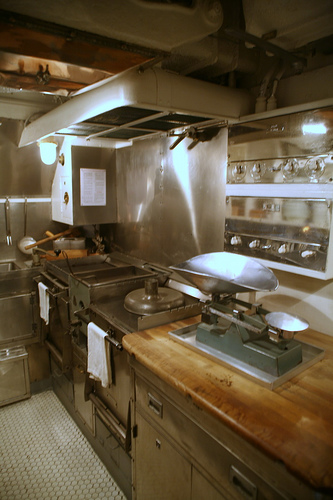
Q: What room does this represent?
A: It represents the kitchen.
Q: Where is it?
A: This is at the kitchen.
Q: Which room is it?
A: It is a kitchen.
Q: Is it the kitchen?
A: Yes, it is the kitchen.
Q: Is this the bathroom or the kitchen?
A: It is the kitchen.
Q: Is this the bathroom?
A: No, it is the kitchen.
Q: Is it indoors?
A: Yes, it is indoors.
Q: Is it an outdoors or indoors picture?
A: It is indoors.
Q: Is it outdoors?
A: No, it is indoors.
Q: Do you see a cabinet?
A: Yes, there is a cabinet.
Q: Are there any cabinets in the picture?
A: Yes, there is a cabinet.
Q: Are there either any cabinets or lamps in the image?
A: Yes, there is a cabinet.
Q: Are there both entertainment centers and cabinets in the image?
A: No, there is a cabinet but no entertainment centers.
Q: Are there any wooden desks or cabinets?
A: Yes, there is a wood cabinet.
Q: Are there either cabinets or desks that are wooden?
A: Yes, the cabinet is wooden.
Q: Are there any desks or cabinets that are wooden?
A: Yes, the cabinet is wooden.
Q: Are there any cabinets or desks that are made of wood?
A: Yes, the cabinet is made of wood.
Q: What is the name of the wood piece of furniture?
A: The piece of furniture is a cabinet.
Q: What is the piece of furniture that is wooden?
A: The piece of furniture is a cabinet.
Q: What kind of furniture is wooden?
A: The furniture is a cabinet.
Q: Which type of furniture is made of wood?
A: The furniture is a cabinet.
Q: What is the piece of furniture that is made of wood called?
A: The piece of furniture is a cabinet.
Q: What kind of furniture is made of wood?
A: The furniture is a cabinet.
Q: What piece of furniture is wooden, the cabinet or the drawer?
A: The cabinet is wooden.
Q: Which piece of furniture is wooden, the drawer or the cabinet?
A: The cabinet is wooden.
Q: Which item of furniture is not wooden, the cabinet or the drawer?
A: The drawer is not wooden.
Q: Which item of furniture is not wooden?
A: The piece of furniture is a drawer.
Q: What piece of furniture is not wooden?
A: The piece of furniture is a drawer.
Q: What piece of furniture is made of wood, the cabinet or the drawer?
A: The cabinet is made of wood.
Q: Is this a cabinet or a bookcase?
A: This is a cabinet.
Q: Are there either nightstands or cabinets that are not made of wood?
A: No, there is a cabinet but it is made of wood.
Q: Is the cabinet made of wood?
A: Yes, the cabinet is made of wood.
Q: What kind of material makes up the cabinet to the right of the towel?
A: The cabinet is made of wood.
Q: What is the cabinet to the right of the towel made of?
A: The cabinet is made of wood.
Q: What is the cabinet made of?
A: The cabinet is made of wood.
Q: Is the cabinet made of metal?
A: No, the cabinet is made of wood.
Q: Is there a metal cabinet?
A: No, there is a cabinet but it is made of wood.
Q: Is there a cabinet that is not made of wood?
A: No, there is a cabinet but it is made of wood.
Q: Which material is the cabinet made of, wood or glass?
A: The cabinet is made of wood.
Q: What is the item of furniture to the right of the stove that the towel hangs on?
A: The piece of furniture is a cabinet.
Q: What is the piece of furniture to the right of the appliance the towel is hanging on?
A: The piece of furniture is a cabinet.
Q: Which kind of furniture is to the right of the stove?
A: The piece of furniture is a cabinet.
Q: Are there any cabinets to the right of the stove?
A: Yes, there is a cabinet to the right of the stove.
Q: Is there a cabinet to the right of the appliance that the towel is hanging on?
A: Yes, there is a cabinet to the right of the stove.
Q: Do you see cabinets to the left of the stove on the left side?
A: No, the cabinet is to the right of the stove.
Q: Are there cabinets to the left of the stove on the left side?
A: No, the cabinet is to the right of the stove.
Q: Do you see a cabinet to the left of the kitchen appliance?
A: No, the cabinet is to the right of the stove.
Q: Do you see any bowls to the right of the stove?
A: No, there is a cabinet to the right of the stove.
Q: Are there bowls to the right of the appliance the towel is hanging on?
A: No, there is a cabinet to the right of the stove.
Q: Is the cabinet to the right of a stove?
A: Yes, the cabinet is to the right of a stove.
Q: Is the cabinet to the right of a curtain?
A: No, the cabinet is to the right of a stove.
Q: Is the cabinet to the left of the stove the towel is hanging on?
A: No, the cabinet is to the right of the stove.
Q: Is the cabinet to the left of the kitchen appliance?
A: No, the cabinet is to the right of the stove.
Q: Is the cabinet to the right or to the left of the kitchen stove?
A: The cabinet is to the right of the stove.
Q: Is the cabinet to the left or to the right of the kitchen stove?
A: The cabinet is to the right of the stove.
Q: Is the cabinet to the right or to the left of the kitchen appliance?
A: The cabinet is to the right of the stove.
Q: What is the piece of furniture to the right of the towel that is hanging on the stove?
A: The piece of furniture is a cabinet.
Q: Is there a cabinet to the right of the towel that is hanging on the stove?
A: Yes, there is a cabinet to the right of the towel.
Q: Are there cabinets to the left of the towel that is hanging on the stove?
A: No, the cabinet is to the right of the towel.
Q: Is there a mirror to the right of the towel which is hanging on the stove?
A: No, there is a cabinet to the right of the towel.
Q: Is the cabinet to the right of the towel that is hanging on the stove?
A: Yes, the cabinet is to the right of the towel.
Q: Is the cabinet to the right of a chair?
A: No, the cabinet is to the right of the towel.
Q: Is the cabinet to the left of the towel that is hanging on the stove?
A: No, the cabinet is to the right of the towel.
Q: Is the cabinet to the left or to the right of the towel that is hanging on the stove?
A: The cabinet is to the right of the towel.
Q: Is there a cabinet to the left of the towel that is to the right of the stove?
A: No, the cabinet is to the right of the towel.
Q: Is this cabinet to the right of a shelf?
A: No, the cabinet is to the right of the towel.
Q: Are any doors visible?
A: Yes, there is a door.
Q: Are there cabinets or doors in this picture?
A: Yes, there is a door.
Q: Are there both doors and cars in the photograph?
A: No, there is a door but no cars.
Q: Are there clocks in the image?
A: No, there are no clocks.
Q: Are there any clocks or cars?
A: No, there are no clocks or cars.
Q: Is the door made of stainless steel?
A: Yes, the door is made of stainless steel.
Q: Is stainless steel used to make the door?
A: Yes, the door is made of stainless steel.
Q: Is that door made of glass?
A: No, the door is made of stainless steel.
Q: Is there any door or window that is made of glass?
A: No, there is a door but it is made of stainless steel.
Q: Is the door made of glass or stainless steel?
A: The door is made of stainless steel.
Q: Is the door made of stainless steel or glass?
A: The door is made of stainless steel.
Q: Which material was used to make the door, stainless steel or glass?
A: The door is made of stainless steel.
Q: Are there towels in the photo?
A: Yes, there is a towel.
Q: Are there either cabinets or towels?
A: Yes, there is a towel.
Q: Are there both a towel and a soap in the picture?
A: No, there is a towel but no soaps.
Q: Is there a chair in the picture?
A: No, there are no chairs.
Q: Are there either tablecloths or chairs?
A: No, there are no chairs or tablecloths.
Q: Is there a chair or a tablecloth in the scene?
A: No, there are no chairs or tablecloths.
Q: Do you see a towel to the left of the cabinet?
A: Yes, there is a towel to the left of the cabinet.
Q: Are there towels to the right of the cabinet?
A: No, the towel is to the left of the cabinet.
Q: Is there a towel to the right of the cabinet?
A: No, the towel is to the left of the cabinet.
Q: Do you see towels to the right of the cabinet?
A: No, the towel is to the left of the cabinet.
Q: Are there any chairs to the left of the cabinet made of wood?
A: No, there is a towel to the left of the cabinet.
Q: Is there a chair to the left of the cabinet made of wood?
A: No, there is a towel to the left of the cabinet.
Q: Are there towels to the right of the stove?
A: Yes, there is a towel to the right of the stove.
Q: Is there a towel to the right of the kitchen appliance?
A: Yes, there is a towel to the right of the stove.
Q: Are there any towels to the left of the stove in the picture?
A: No, the towel is to the right of the stove.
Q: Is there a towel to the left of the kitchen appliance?
A: No, the towel is to the right of the stove.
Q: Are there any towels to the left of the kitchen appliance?
A: No, the towel is to the right of the stove.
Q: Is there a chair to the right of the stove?
A: No, there is a towel to the right of the stove.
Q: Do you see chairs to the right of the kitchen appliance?
A: No, there is a towel to the right of the stove.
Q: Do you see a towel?
A: Yes, there is a towel.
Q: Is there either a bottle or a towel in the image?
A: Yes, there is a towel.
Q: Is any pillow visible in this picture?
A: No, there are no pillows.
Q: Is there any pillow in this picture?
A: No, there are no pillows.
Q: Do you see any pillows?
A: No, there are no pillows.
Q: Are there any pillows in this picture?
A: No, there are no pillows.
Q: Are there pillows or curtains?
A: No, there are no pillows or curtains.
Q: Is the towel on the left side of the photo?
A: Yes, the towel is on the left of the image.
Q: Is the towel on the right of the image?
A: No, the towel is on the left of the image.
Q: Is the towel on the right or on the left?
A: The towel is on the left of the image.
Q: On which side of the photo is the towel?
A: The towel is on the left of the image.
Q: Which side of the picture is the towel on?
A: The towel is on the left of the image.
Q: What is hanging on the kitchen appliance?
A: The towel is hanging on the stove.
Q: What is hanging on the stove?
A: The towel is hanging on the stove.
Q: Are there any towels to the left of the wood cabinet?
A: Yes, there is a towel to the left of the cabinet.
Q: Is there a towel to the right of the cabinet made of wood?
A: No, the towel is to the left of the cabinet.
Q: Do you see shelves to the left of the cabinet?
A: No, there is a towel to the left of the cabinet.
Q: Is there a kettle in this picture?
A: No, there are no kettles.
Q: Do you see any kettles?
A: No, there are no kettles.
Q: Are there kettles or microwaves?
A: No, there are no kettles or microwaves.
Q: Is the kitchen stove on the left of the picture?
A: Yes, the stove is on the left of the image.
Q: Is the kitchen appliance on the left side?
A: Yes, the stove is on the left of the image.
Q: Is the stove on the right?
A: No, the stove is on the left of the image.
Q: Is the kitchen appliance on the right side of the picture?
A: No, the stove is on the left of the image.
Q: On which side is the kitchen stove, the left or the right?
A: The stove is on the left of the image.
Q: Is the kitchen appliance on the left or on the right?
A: The stove is on the left of the image.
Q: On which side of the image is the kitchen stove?
A: The stove is on the left of the image.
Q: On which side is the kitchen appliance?
A: The stove is on the left of the image.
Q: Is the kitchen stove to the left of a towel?
A: Yes, the stove is to the left of a towel.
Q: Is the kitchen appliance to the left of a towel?
A: Yes, the stove is to the left of a towel.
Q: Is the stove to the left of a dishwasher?
A: No, the stove is to the left of a towel.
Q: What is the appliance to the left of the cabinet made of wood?
A: The appliance is a stove.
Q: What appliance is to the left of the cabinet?
A: The appliance is a stove.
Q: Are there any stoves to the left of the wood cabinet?
A: Yes, there is a stove to the left of the cabinet.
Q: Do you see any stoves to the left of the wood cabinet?
A: Yes, there is a stove to the left of the cabinet.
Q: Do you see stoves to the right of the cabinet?
A: No, the stove is to the left of the cabinet.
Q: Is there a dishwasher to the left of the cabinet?
A: No, there is a stove to the left of the cabinet.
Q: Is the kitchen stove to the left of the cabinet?
A: Yes, the stove is to the left of the cabinet.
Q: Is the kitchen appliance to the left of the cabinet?
A: Yes, the stove is to the left of the cabinet.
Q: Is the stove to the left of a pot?
A: No, the stove is to the left of the cabinet.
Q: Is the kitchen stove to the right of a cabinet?
A: No, the stove is to the left of a cabinet.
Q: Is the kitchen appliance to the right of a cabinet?
A: No, the stove is to the left of a cabinet.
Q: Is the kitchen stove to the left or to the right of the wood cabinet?
A: The stove is to the left of the cabinet.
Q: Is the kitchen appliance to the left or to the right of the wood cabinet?
A: The stove is to the left of the cabinet.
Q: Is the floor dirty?
A: Yes, the floor is dirty.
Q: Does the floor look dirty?
A: Yes, the floor is dirty.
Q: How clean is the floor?
A: The floor is dirty.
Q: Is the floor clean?
A: No, the floor is dirty.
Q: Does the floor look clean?
A: No, the floor is dirty.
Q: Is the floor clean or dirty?
A: The floor is dirty.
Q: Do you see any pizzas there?
A: No, there are no pizzas.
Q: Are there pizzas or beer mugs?
A: No, there are no pizzas or beer mugs.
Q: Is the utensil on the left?
A: Yes, the utensil is on the left of the image.